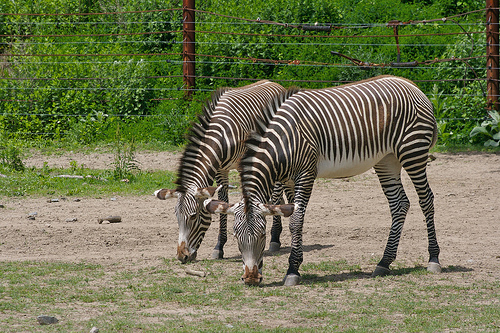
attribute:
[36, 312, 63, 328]
rock — gray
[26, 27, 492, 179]
fence — brown, metal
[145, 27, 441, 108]
pole — metal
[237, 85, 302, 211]
mane — striped, white, black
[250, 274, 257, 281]
nose — brown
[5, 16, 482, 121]
fence — metal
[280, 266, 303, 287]
hoof — gray